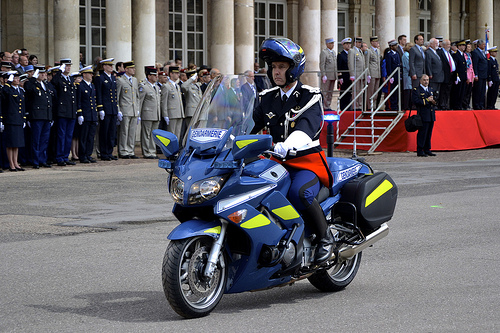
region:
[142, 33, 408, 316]
a soldier on a motorcycle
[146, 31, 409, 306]
a policeman on a motorcycle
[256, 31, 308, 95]
a helmet on a man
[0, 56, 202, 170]
military people standing together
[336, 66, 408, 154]
stairs leading to a stage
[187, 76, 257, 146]
a windshield on a motorcycle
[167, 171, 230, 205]
headlights on a motorcycle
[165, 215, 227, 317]
tire on a motorcycle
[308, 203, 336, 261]
a boot on a man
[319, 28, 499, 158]
people standing on a stage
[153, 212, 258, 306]
the wheels on a bike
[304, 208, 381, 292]
the back wheel on a bike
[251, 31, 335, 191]
A person in uniform on motorcycle.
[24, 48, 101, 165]
People saluting to the crowd.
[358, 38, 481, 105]
People standing on the stand.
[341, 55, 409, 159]
stairs to the stage.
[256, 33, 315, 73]
The man is wearing a blue helmet.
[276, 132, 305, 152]
The man has white gloves.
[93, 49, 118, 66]
The man is wearing a white hat.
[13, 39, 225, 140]
People standing in front of the building.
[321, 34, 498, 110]
group of people standing on a red platform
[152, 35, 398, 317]
man riding on a blue motorcycle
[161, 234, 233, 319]
front wheel of the motorcycle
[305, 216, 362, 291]
back wheel of the motorcycle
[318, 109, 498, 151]
red band stand with people standing on it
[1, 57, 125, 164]
military in blue and white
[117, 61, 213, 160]
men dressed in suits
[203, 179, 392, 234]
yellow strip down the side of the motorcycle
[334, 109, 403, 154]
steps leading to the band stand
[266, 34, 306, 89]
blue and black helmet man is wearing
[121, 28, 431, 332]
he is on a motorcycle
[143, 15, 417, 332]
he is wearing a large helmet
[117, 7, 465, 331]
the motorcycle has green stripes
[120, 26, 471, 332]
a blue and neon green motorcycle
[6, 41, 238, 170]
they are all dressed in a uniform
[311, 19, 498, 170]
they are standing on a stage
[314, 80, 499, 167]
the stage is red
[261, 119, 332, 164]
his gloves are white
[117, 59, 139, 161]
A person is standing up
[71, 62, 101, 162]
A person is standing up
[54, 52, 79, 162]
A person is standing up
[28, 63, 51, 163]
A person is standing up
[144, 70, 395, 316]
a motorcycle on a road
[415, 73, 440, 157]
a person is standing up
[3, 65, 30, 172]
a person is standing up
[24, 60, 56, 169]
a person is standing up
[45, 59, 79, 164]
a person is standing up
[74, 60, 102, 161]
a person is standing up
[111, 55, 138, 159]
a person is standing up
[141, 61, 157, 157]
a person is standing up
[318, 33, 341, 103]
a person is standing up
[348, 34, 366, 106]
a person is standing up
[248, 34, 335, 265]
the man riding the motorcycle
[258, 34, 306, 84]
the blue helmet on the man's head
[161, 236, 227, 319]
the front wheel of the motorcycle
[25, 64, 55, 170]
a man in uniform saluting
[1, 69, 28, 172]
a woman in uniform saluting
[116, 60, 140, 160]
a man wearing light gray uniform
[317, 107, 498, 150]
red fabric covering the platform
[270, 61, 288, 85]
Face of a man